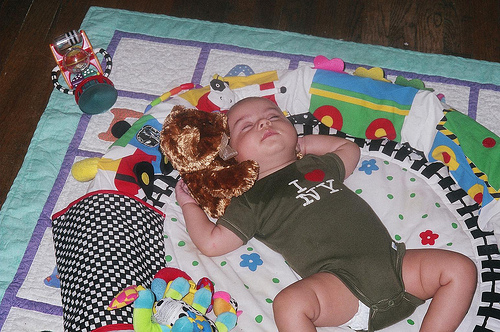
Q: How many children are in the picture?
A: One.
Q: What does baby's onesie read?
A: I [heart] NY.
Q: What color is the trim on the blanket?
A: Blue.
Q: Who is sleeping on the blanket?
A: A baby.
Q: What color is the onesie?
A: Olive.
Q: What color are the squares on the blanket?
A: White and purple.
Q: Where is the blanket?
A: On the floor.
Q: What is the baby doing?
A: Sleeping.